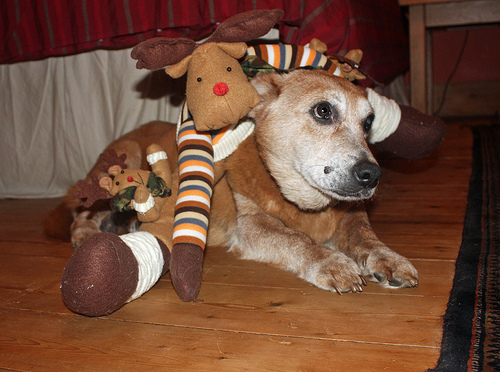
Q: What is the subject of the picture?
A: Dog.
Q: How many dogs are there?
A: One.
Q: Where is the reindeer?
A: On dog.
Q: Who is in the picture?
A: No one.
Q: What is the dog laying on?
A: Floor.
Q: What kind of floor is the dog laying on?
A: Wood.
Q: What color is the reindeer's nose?
A: Red.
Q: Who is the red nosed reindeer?
A: Rudolph.